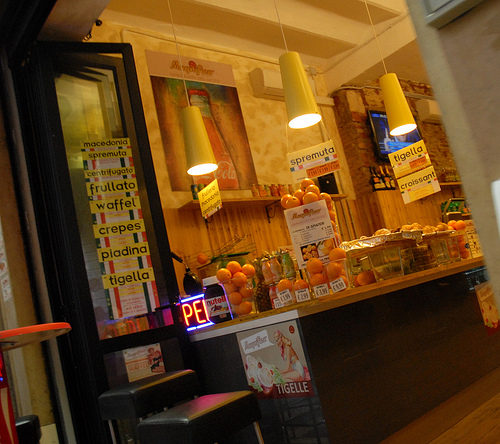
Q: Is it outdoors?
A: Yes, it is outdoors.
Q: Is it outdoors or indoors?
A: It is outdoors.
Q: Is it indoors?
A: No, it is outdoors.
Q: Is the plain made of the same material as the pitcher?
A: Yes, both the plain and the pitcher are made of glass.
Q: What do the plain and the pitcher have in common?
A: The material, both the plain and the pitcher are glass.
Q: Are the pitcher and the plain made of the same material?
A: Yes, both the pitcher and the plain are made of glass.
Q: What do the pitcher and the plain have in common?
A: The material, both the pitcher and the plain are glass.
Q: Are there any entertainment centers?
A: No, there are no entertainment centers.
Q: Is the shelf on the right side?
A: Yes, the shelf is on the right of the image.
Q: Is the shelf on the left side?
A: No, the shelf is on the right of the image.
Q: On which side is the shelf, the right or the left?
A: The shelf is on the right of the image.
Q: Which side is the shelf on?
A: The shelf is on the right of the image.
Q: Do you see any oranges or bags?
A: Yes, there are oranges.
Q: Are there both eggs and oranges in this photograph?
A: No, there are oranges but no eggs.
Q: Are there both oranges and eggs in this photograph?
A: No, there are oranges but no eggs.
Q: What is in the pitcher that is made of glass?
A: The oranges are in the pitcher.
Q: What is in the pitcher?
A: The oranges are in the pitcher.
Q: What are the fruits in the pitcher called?
A: The fruits are oranges.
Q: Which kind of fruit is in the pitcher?
A: The fruits are oranges.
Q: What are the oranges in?
A: The oranges are in the pitcher.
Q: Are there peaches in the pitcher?
A: No, there are oranges in the pitcher.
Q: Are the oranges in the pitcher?
A: Yes, the oranges are in the pitcher.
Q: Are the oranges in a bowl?
A: No, the oranges are in the pitcher.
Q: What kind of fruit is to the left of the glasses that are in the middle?
A: The fruits are oranges.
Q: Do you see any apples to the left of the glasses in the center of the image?
A: No, there are oranges to the left of the glasses.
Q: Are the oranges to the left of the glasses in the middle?
A: Yes, the oranges are to the left of the glasses.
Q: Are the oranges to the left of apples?
A: No, the oranges are to the left of the glasses.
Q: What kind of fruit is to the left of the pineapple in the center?
A: The fruits are oranges.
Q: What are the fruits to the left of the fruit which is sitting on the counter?
A: The fruits are oranges.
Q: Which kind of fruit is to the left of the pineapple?
A: The fruits are oranges.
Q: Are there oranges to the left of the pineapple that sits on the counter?
A: Yes, there are oranges to the left of the pineapple.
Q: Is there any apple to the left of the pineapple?
A: No, there are oranges to the left of the pineapple.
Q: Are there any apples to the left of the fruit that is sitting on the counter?
A: No, there are oranges to the left of the pineapple.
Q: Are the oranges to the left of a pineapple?
A: Yes, the oranges are to the left of a pineapple.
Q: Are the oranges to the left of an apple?
A: No, the oranges are to the left of a pineapple.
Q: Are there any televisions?
A: Yes, there is a television.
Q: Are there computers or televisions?
A: Yes, there is a television.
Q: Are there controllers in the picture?
A: No, there are no controllers.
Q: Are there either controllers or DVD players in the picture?
A: No, there are no controllers or DVD players.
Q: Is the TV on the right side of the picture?
A: Yes, the TV is on the right of the image.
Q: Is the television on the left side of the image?
A: No, the television is on the right of the image.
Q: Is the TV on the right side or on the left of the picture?
A: The TV is on the right of the image.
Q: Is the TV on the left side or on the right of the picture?
A: The TV is on the right of the image.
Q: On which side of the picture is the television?
A: The television is on the right of the image.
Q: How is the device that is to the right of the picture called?
A: The device is a television.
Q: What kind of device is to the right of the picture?
A: The device is a television.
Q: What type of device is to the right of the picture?
A: The device is a television.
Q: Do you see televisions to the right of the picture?
A: Yes, there is a television to the right of the picture.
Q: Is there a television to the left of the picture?
A: No, the television is to the right of the picture.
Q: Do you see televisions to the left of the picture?
A: No, the television is to the right of the picture.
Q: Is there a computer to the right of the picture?
A: No, there is a television to the right of the picture.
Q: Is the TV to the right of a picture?
A: Yes, the TV is to the right of a picture.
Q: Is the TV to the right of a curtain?
A: No, the TV is to the right of a picture.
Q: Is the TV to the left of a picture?
A: No, the TV is to the right of a picture.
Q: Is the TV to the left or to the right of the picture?
A: The TV is to the right of the picture.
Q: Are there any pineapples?
A: Yes, there is a pineapple.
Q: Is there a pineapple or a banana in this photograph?
A: Yes, there is a pineapple.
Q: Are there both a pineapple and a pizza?
A: No, there is a pineapple but no pizzas.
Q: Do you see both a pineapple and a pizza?
A: No, there is a pineapple but no pizzas.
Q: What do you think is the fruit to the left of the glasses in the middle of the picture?
A: The fruit is a pineapple.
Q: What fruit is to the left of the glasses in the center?
A: The fruit is a pineapple.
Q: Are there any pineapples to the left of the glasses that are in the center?
A: Yes, there is a pineapple to the left of the glasses.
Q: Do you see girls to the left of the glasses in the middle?
A: No, there is a pineapple to the left of the glasses.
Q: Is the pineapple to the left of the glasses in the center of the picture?
A: Yes, the pineapple is to the left of the glasses.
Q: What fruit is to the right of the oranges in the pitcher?
A: The fruit is a pineapple.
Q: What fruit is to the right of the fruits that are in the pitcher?
A: The fruit is a pineapple.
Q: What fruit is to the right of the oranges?
A: The fruit is a pineapple.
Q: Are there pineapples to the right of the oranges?
A: Yes, there is a pineapple to the right of the oranges.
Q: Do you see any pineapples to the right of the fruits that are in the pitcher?
A: Yes, there is a pineapple to the right of the oranges.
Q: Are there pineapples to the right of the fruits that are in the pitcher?
A: Yes, there is a pineapple to the right of the oranges.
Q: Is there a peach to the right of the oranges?
A: No, there is a pineapple to the right of the oranges.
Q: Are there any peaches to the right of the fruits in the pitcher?
A: No, there is a pineapple to the right of the oranges.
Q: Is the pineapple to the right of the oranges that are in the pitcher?
A: Yes, the pineapple is to the right of the oranges.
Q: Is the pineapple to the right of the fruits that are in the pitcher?
A: Yes, the pineapple is to the right of the oranges.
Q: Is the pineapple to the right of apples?
A: No, the pineapple is to the right of the oranges.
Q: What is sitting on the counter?
A: The pineapple is sitting on the counter.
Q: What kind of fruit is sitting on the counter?
A: The fruit is a pineapple.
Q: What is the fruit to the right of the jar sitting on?
A: The pineapple is sitting on the counter.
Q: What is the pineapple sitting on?
A: The pineapple is sitting on the counter.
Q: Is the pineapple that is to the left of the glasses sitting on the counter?
A: Yes, the pineapple is sitting on the counter.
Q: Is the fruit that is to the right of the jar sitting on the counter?
A: Yes, the pineapple is sitting on the counter.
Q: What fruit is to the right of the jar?
A: The fruit is a pineapple.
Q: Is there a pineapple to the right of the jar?
A: Yes, there is a pineapple to the right of the jar.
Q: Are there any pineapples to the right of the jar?
A: Yes, there is a pineapple to the right of the jar.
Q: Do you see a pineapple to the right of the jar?
A: Yes, there is a pineapple to the right of the jar.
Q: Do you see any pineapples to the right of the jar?
A: Yes, there is a pineapple to the right of the jar.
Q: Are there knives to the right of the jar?
A: No, there is a pineapple to the right of the jar.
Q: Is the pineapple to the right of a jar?
A: Yes, the pineapple is to the right of a jar.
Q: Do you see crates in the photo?
A: No, there are no crates.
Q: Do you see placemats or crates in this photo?
A: No, there are no crates or placemats.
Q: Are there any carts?
A: No, there are no carts.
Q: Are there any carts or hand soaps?
A: No, there are no carts or hand soaps.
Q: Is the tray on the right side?
A: Yes, the tray is on the right of the image.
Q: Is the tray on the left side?
A: No, the tray is on the right of the image.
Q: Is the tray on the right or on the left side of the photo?
A: The tray is on the right of the image.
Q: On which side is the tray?
A: The tray is on the right of the image.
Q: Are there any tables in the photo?
A: Yes, there is a table.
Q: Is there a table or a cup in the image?
A: Yes, there is a table.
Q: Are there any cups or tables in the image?
A: Yes, there is a table.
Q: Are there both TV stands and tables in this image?
A: No, there is a table but no TV stands.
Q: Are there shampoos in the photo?
A: No, there are no shampoos.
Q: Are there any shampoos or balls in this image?
A: No, there are no shampoos or balls.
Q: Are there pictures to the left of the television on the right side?
A: Yes, there is a picture to the left of the television.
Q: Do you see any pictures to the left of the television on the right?
A: Yes, there is a picture to the left of the television.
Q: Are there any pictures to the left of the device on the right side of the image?
A: Yes, there is a picture to the left of the television.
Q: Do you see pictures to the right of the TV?
A: No, the picture is to the left of the TV.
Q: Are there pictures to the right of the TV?
A: No, the picture is to the left of the TV.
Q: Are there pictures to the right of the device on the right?
A: No, the picture is to the left of the TV.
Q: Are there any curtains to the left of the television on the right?
A: No, there is a picture to the left of the television.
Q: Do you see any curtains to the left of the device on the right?
A: No, there is a picture to the left of the television.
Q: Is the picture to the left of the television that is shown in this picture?
A: Yes, the picture is to the left of the television.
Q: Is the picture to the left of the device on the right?
A: Yes, the picture is to the left of the television.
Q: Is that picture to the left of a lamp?
A: No, the picture is to the left of the television.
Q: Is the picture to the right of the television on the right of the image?
A: No, the picture is to the left of the television.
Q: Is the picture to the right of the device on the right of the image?
A: No, the picture is to the left of the television.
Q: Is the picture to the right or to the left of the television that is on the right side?
A: The picture is to the left of the TV.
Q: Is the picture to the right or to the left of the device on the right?
A: The picture is to the left of the TV.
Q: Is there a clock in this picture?
A: No, there are no clocks.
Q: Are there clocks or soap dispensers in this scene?
A: No, there are no clocks or soap dispensers.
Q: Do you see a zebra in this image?
A: No, there are no zebras.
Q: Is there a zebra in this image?
A: No, there are no zebras.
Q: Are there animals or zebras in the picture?
A: No, there are no zebras or animals.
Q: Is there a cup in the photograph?
A: No, there are no cups.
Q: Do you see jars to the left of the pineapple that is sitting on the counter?
A: Yes, there is a jar to the left of the pineapple.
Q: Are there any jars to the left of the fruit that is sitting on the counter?
A: Yes, there is a jar to the left of the pineapple.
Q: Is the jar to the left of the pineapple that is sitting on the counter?
A: Yes, the jar is to the left of the pineapple.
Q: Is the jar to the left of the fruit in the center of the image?
A: Yes, the jar is to the left of the pineapple.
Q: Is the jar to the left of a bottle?
A: No, the jar is to the left of the pineapple.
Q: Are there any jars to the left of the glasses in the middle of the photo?
A: Yes, there is a jar to the left of the glasses.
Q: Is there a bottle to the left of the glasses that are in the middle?
A: No, there is a jar to the left of the glasses.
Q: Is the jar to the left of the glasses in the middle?
A: Yes, the jar is to the left of the glasses.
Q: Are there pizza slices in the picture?
A: No, there are no pizza slices.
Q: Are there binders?
A: No, there are no binders.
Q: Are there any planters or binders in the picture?
A: No, there are no binders or planters.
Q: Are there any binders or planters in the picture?
A: No, there are no binders or planters.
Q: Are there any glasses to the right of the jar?
A: Yes, there are glasses to the right of the jar.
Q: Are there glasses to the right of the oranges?
A: Yes, there are glasses to the right of the oranges.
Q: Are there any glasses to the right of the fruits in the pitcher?
A: Yes, there are glasses to the right of the oranges.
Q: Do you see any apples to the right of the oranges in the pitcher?
A: No, there are glasses to the right of the oranges.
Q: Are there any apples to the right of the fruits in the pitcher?
A: No, there are glasses to the right of the oranges.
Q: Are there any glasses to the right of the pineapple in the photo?
A: Yes, there are glasses to the right of the pineapple.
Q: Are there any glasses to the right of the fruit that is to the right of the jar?
A: Yes, there are glasses to the right of the pineapple.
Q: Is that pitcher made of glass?
A: Yes, the pitcher is made of glass.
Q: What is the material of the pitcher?
A: The pitcher is made of glass.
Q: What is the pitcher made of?
A: The pitcher is made of glass.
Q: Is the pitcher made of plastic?
A: No, the pitcher is made of glass.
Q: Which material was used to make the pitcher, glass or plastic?
A: The pitcher is made of glass.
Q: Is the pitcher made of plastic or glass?
A: The pitcher is made of glass.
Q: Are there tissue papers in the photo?
A: No, there are no tissue papers.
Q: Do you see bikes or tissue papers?
A: No, there are no tissue papers or bikes.